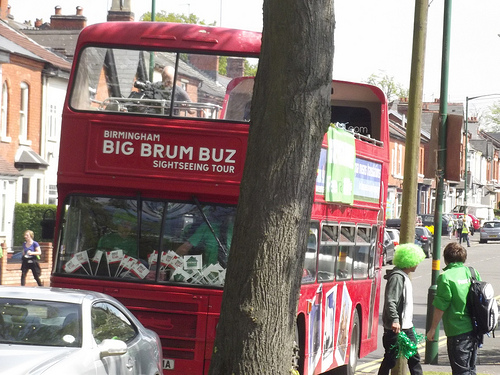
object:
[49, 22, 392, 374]
bus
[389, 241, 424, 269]
wig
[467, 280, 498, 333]
backpack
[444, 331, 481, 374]
pants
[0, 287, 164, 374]
car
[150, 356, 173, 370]
license plate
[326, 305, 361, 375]
wheel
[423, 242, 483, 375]
person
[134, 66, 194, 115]
man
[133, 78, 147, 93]
camera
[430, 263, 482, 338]
jacket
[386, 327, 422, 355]
pom poms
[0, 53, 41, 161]
wall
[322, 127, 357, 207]
banner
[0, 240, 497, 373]
road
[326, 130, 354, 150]
sign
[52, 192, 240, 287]
windshield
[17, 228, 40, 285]
pedestrian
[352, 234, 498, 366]
street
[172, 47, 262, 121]
window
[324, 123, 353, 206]
towel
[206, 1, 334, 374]
stem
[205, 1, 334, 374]
tree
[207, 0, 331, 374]
bark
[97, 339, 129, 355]
mirror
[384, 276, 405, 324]
arm